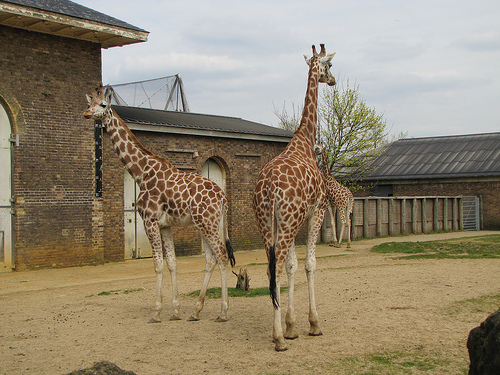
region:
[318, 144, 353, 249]
Baby giraffe looking over fence.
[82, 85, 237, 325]
Young "teen ager" giraffe, staying close to Mom.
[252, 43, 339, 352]
Mom giraffe keeping a watchful eye on baby.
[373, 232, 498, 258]
Patch of grass, worn down from being eaten and trampled.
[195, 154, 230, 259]
Old doorway in old brick building, possibly their sleeping area.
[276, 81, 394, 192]
Young tree just starting to bloom.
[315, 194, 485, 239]
Flimsy fence and access gate.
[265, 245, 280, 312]
Long black tassel on end of Mom's tail.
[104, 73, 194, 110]
Netting on other side of building, possibly a cage.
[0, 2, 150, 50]
Old and worn eaves of old brick building.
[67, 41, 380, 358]
three giraffe in the yard walking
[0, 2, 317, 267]
giraffe house in the left side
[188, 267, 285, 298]
small tree stump in grass in the yard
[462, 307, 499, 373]
big rock on side of giraffe yard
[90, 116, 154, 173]
giraffe long neck with spots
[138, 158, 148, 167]
one spot on giraffe long neck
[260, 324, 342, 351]
hooves on giraffe long legs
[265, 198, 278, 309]
long tail of giraffe in the back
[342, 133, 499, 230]
other house in the background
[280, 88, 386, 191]
large tree in between both house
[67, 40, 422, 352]
3 giraffes standing around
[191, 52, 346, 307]
the giraffe is brown and white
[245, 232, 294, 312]
the tip of the tail is black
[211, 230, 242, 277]
hair is at the tip of the tail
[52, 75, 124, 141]
the giraffe is looking at the camera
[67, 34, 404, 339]
the giraffes are at the zoo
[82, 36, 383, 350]
the giraffes are in captivity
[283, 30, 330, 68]
the giraffe has horns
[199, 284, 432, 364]
the giraffe is standing on sand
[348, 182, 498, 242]
the gate is short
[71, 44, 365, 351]
giraffes standing on the dirt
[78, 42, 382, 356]
group of three giraffes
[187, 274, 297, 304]
small patch of grass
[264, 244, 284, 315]
long black hair on the bottom of the tail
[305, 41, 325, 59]
two small horns on top of the head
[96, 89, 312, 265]
small brick building with a black roof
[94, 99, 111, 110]
small black eye on the side of the head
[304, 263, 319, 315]
no spots on the bottom of the leg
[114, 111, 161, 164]
hair along the back of the neck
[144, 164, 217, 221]
brown spots on the skin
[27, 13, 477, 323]
giraffes inside of an area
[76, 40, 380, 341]
there are three giraffes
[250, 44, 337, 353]
a giraffe is a long animal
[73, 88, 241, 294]
this giraffe is oberving something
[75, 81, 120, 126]
the giraffe's head is observant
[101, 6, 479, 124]
a cloudy day over the area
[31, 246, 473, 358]
dirty ground beneath the giraffes hooves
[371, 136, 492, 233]
a building in the area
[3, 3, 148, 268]
a brick building behind the giraffes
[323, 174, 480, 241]
a gate for the giraffes